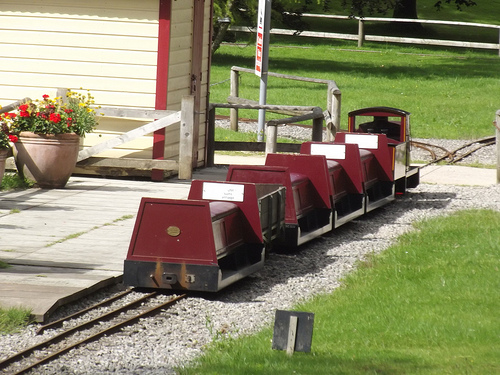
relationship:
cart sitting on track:
[114, 103, 419, 292] [2, 136, 480, 373]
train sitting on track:
[119, 102, 421, 293] [2, 136, 480, 373]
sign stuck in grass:
[273, 306, 313, 356] [172, 205, 484, 373]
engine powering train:
[354, 131, 410, 185] [119, 102, 421, 293]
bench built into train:
[202, 191, 252, 263] [119, 102, 421, 293]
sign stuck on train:
[202, 181, 245, 202] [119, 102, 421, 293]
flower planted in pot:
[46, 111, 63, 124] [8, 131, 81, 189]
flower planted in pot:
[6, 134, 19, 143] [8, 131, 81, 189]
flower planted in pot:
[17, 103, 30, 113] [8, 131, 81, 189]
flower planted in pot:
[53, 95, 62, 102] [8, 131, 81, 189]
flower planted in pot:
[79, 102, 88, 109] [8, 131, 81, 189]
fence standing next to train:
[208, 64, 341, 164] [119, 102, 421, 293]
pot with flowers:
[14, 128, 81, 185] [5, 87, 97, 148]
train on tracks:
[119, 102, 421, 293] [1, 280, 183, 371]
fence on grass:
[312, 10, 469, 53] [198, 0, 500, 371]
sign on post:
[255, 7, 265, 70] [250, 81, 268, 140]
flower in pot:
[17, 103, 30, 113] [14, 136, 87, 186]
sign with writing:
[255, 7, 265, 70] [254, 7, 260, 68]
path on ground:
[32, 179, 471, 372] [154, 324, 219, 364]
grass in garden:
[375, 266, 458, 359] [21, 18, 495, 375]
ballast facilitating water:
[74, 293, 216, 353] [134, 89, 464, 290]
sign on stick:
[252, 4, 275, 97] [84, 119, 184, 151]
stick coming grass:
[84, 119, 184, 151] [374, 273, 442, 353]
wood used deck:
[117, 110, 179, 138] [0, 173, 251, 325]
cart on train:
[346, 97, 412, 180] [119, 102, 421, 293]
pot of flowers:
[14, 128, 81, 185] [5, 90, 101, 172]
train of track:
[119, 102, 421, 293] [5, 297, 167, 373]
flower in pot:
[79, 102, 88, 109] [15, 129, 79, 188]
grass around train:
[198, 0, 500, 371] [119, 102, 421, 293]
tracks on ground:
[0, 136, 500, 373] [1, 36, 496, 370]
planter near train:
[7, 129, 85, 190] [119, 102, 421, 293]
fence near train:
[221, 8, 494, 48] [119, 102, 421, 293]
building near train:
[3, 0, 217, 174] [119, 102, 421, 293]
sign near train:
[255, 7, 265, 70] [119, 102, 421, 293]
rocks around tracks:
[2, 115, 497, 368] [0, 109, 500, 368]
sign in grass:
[273, 306, 313, 356] [182, 200, 497, 369]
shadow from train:
[203, 186, 461, 307] [119, 102, 421, 293]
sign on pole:
[251, 0, 267, 80] [253, 0, 267, 144]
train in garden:
[119, 102, 421, 293] [31, 22, 492, 362]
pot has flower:
[14, 128, 81, 185] [79, 102, 88, 109]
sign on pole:
[247, 0, 268, 87] [248, 0, 277, 146]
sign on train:
[202, 181, 245, 202] [119, 102, 421, 293]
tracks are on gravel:
[1, 280, 183, 371] [1, 181, 490, 371]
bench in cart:
[202, 191, 252, 263] [120, 171, 276, 293]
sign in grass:
[273, 306, 313, 356] [204, 210, 492, 373]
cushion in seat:
[210, 194, 242, 221] [192, 196, 260, 266]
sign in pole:
[246, 2, 268, 79] [253, 0, 270, 143]